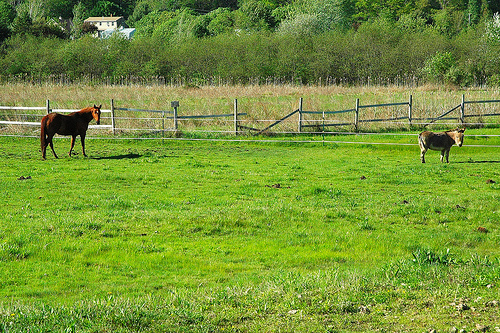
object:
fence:
[0, 94, 500, 136]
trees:
[0, 0, 500, 78]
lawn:
[40, 163, 480, 315]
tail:
[418, 135, 427, 152]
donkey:
[416, 126, 465, 164]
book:
[38, 103, 105, 159]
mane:
[75, 108, 93, 115]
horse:
[39, 103, 102, 160]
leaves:
[174, 41, 316, 66]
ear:
[94, 104, 96, 109]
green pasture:
[0, 132, 499, 333]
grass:
[0, 125, 497, 333]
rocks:
[411, 294, 499, 331]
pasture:
[2, 129, 499, 331]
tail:
[39, 117, 48, 152]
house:
[82, 16, 135, 41]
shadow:
[448, 159, 498, 162]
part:
[252, 107, 273, 125]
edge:
[0, 308, 498, 333]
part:
[416, 137, 428, 145]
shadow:
[91, 152, 144, 160]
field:
[0, 127, 500, 333]